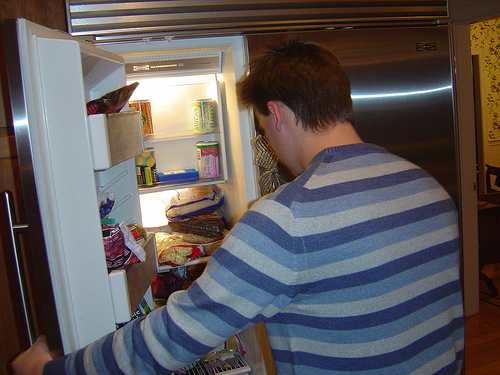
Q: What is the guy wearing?
A: A blue striped sweater.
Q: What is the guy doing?
A: Looking in the freezer.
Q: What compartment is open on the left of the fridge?
A: The freezer.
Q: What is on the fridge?
A: Handle.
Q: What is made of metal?
A: Handle.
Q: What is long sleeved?
A: Sweater.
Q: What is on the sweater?
A: Stripes.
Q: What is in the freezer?
A: Food.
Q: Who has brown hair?
A: The man.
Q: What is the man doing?
A: Looking at the food.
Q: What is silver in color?
A: The door.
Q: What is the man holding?
A: Handle of the fridge.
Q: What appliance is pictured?
A: Refrigerator.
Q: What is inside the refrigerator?
A: Food.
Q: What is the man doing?
A: Looking in the refrigerator.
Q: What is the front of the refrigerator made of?
A: Stainless steel.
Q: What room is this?
A: Kitchen.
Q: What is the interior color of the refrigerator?
A: White.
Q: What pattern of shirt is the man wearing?
A: Striped.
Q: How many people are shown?
A: One.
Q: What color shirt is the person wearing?
A: Blue and gray.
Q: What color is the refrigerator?
A: Silver.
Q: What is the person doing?
A: Looking in refrigerator.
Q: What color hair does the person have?
A: Brown.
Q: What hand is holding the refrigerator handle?
A: Left hand.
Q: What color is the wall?
A: Yellow with flowers.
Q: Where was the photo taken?
A: In a house.